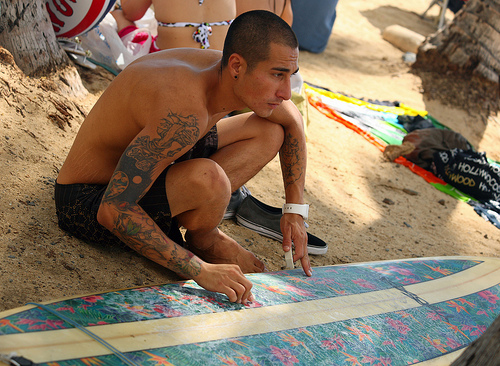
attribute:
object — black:
[435, 141, 499, 203]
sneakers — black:
[217, 183, 249, 221]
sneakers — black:
[235, 190, 328, 255]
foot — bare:
[199, 231, 249, 280]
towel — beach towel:
[303, 81, 498, 228]